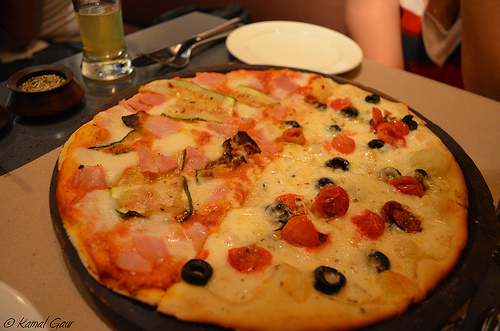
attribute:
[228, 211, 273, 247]
cheese — white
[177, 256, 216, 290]
olive — black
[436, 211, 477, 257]
crust — crispy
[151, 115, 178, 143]
ham — pink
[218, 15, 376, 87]
white plate — small, round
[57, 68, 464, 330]
pizza — crispy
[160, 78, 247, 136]
zucchini — green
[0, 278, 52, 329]
plate — small, white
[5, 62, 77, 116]
bowl — small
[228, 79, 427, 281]
tomatoes — red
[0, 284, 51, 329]
plate — white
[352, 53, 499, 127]
table — brown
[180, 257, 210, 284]
olives — black